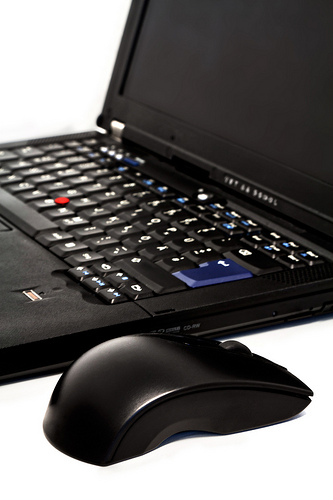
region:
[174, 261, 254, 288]
The button on the keyboard is blue.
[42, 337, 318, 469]
The mouse is black in color.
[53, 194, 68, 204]
The button on the keyboard is red.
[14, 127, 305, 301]
The numbers, symbols and letters on the keyboard are white.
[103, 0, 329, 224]
The laptop monitor is black.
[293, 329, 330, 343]
The table is white in color.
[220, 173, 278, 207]
The writing on the monitor is white.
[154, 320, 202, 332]
The writing on the side of the laptop is white.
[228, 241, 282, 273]
The button on the laptop is black and white.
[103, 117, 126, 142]
The hinges on the laptop are silver.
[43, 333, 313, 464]
black computer mouse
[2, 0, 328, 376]
black laptop computer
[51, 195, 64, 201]
red pointing stick on the IBM ThinkPad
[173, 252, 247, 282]
blue enter key on the laptop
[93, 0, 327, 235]
laptop screen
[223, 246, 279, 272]
backspace key on the keyboard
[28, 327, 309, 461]
black wireless mouse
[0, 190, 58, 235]
black spacebar on the laptop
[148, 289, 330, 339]
CD-RW drive on the side of the laptop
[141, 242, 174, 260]
the A key on the keyboard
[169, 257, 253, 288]
A dark blue enter key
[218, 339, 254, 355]
A black mouse wheel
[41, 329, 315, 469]
A black computer mouse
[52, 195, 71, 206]
A red cursor control button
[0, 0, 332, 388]
A black laptop computer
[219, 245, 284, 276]
A black back space key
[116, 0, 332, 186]
A black powered off laptop screen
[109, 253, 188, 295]
A black shift key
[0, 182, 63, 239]
A black space bar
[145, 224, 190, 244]
A black P key on a laptop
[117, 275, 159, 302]
key on a keyboard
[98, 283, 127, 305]
key on a keyboard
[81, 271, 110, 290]
key on a keyboard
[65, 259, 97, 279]
key on a keyboard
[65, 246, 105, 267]
key on a keyboard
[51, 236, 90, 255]
key on a keyboard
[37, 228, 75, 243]
key on a keyboard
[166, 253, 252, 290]
key on a keyboard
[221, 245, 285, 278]
key on a keyboard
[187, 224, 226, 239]
key on a keyboard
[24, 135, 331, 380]
Keyboard on the laptop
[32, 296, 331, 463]
Mouse beside the laptop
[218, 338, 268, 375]
Track ball on the mouse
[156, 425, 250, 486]
Light under the mouse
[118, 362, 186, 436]
Light reflection on the mouse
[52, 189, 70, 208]
Red key on the keyboard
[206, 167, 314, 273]
Company name on the screen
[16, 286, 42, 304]
Finger print scanner on laptop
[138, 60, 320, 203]
Screen on the laptop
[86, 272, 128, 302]
Keys on keyboard